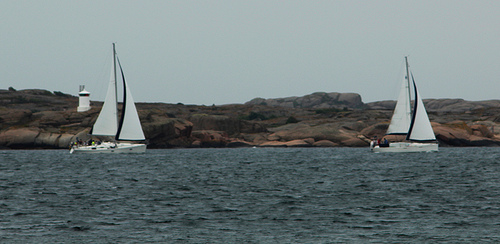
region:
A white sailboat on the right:
[351, 50, 462, 172]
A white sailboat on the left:
[93, 53, 148, 165]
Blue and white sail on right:
[408, 77, 431, 140]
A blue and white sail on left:
[110, 50, 150, 155]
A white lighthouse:
[58, 72, 96, 119]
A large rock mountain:
[281, 90, 370, 113]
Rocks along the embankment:
[258, 121, 322, 146]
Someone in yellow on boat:
[81, 134, 102, 153]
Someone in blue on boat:
[379, 137, 391, 147]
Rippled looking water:
[158, 163, 345, 234]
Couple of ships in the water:
[66, 41, 441, 154]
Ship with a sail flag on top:
[62, 43, 149, 154]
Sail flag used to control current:
[91, 39, 146, 141]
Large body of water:
[1, 145, 497, 241]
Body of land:
[1, 85, 498, 145]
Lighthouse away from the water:
[74, 82, 93, 115]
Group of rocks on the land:
[237, 84, 497, 106]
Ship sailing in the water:
[69, 43, 149, 152]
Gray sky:
[0, 0, 497, 105]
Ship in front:
[352, 53, 442, 153]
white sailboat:
[74, 43, 151, 161]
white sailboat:
[377, 38, 459, 173]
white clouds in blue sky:
[8, 16, 55, 93]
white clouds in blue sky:
[55, 15, 86, 77]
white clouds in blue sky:
[151, 21, 182, 102]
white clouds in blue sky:
[187, 13, 219, 91]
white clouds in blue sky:
[228, 11, 292, 92]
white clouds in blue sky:
[297, 18, 325, 73]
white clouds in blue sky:
[337, 13, 372, 90]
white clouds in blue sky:
[428, 21, 463, 72]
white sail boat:
[75, 45, 149, 163]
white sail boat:
[378, 49, 429, 156]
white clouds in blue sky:
[24, 21, 46, 68]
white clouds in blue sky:
[188, 31, 212, 73]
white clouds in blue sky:
[157, 43, 195, 94]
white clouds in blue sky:
[237, 0, 271, 60]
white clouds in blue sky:
[307, 29, 347, 73]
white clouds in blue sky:
[320, 21, 365, 81]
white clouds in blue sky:
[450, 43, 471, 80]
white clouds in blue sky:
[318, 41, 355, 71]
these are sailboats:
[16, 18, 486, 238]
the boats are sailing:
[55, 35, 453, 170]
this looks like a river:
[36, 68, 404, 236]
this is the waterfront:
[179, 100, 295, 132]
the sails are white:
[88, 49, 158, 151]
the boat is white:
[75, 135, 165, 160]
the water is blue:
[138, 152, 382, 242]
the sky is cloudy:
[61, 1, 360, 106]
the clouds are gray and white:
[154, 10, 362, 86]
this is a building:
[71, 82, 88, 114]